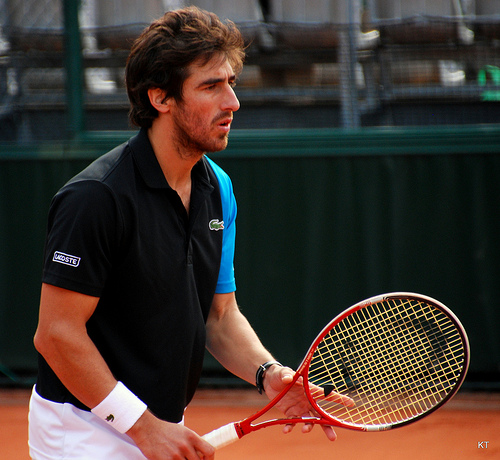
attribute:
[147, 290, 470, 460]
racket — red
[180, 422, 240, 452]
handle — white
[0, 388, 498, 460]
ground — red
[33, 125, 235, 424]
shirt — black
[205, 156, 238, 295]
sleeve — blue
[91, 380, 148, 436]
sweatband — white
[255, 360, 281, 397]
wristwatch — black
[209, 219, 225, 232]
logo — green, alligator